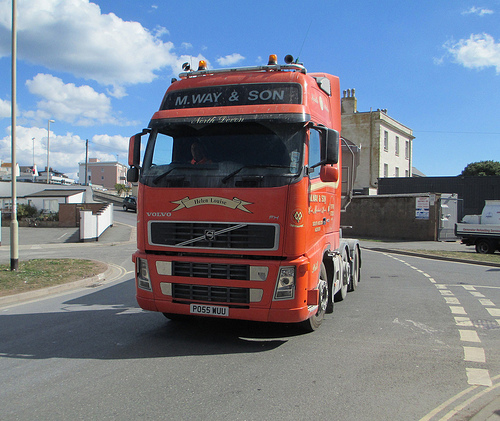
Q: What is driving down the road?
A: A bus.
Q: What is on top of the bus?
A: Lights.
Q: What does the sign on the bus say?
A: M. way & son.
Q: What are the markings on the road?
A: Lines and dashes.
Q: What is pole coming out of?
A: The ground.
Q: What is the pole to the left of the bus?
A: A light pole.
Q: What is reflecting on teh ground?
A: A shadow.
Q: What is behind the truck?
A: A building.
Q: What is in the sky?
A: The clouds.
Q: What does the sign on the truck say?
A: M.Way and Son.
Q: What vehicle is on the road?
A: Truck.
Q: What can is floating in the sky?
A: Clouds.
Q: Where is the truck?
A: On the road.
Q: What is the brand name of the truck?
A: Volvo.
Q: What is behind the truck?
A: A building.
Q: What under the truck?
A: Wheels.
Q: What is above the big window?
A: Letters.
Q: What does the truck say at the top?
A: M. WAY & SON.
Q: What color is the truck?
A: Orange.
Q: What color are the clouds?
A: White.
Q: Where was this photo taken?
A: Road.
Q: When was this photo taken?
A: Daytime.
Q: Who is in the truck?
A: Truck driver.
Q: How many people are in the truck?
A: One.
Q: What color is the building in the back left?
A: White.